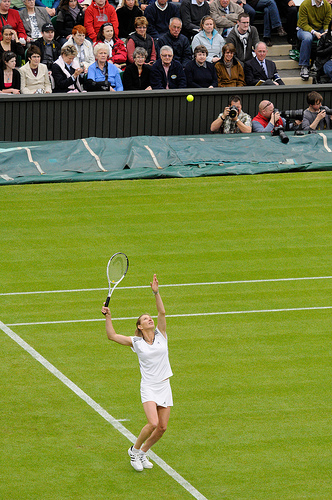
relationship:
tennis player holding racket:
[103, 272, 176, 474] [95, 250, 135, 310]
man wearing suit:
[243, 41, 285, 87] [247, 58, 281, 85]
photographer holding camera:
[207, 94, 249, 137] [225, 105, 239, 120]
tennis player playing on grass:
[103, 272, 176, 474] [2, 179, 330, 499]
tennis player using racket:
[103, 272, 176, 474] [95, 250, 135, 310]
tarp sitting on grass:
[1, 129, 328, 183] [2, 179, 330, 499]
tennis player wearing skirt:
[103, 272, 176, 474] [138, 380, 176, 411]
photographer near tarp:
[207, 94, 249, 137] [1, 129, 328, 183]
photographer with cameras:
[207, 94, 249, 137] [215, 105, 306, 144]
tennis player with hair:
[103, 272, 176, 474] [71, 25, 87, 40]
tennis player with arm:
[103, 272, 176, 474] [84, 62, 110, 90]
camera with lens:
[225, 105, 239, 120] [229, 111, 236, 117]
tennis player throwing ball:
[125, 312, 176, 474] [185, 95, 194, 103]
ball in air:
[185, 95, 194, 103] [72, 84, 311, 213]